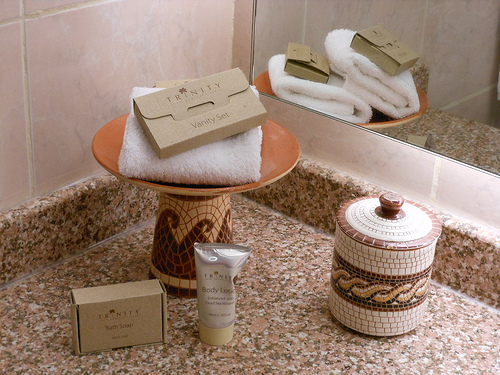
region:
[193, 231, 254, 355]
Squeezed tube on top of a counter.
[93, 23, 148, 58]
Squeezed tube on top of a counter.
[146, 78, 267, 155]
trinity is in a box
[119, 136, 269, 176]
the towewl is white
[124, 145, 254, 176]
the towel is folded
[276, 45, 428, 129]
towels are in the reflection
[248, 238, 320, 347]
the counter is marbled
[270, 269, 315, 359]
the counter is brown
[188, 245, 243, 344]
the bodylotion is upside down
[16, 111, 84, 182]
the wall is tiled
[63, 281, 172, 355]
the box is brown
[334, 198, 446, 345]
the container is brown and white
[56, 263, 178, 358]
a little box of soap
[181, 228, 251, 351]
a tube of beauty cream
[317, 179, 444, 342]
a round container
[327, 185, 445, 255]
cover of container is brown and white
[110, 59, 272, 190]
a small box over a white towel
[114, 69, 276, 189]
a folded white towel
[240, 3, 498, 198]
a mirror on right side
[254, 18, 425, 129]
two towels are reflected on mirror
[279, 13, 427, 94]
two brown boxes on white towels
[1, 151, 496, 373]
counter is color brown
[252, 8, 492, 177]
mirror above countertop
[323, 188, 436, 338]
jar with lid on counter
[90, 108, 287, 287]
stand with white towel on it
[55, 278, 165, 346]
cardboard soap box on counter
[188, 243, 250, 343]
squeeze bottle of lotion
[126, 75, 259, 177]
folded white towel on platter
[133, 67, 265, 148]
cardboard box on top of towel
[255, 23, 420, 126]
reflection of towels in mirror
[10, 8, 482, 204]
tiles on the bathroom walls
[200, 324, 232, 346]
cap of squeeze tube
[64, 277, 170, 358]
Small brown Trinity box on the counter.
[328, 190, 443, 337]
A decorative ceramic container with lid.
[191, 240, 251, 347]
A silver and yellow tube of body lotion.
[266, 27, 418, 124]
Two white folded hand towels in the orange dish reflecting in the mirror.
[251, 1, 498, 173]
A mirror on the right.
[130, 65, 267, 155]
The brown larger Trinity box on the top towel.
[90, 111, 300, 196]
Round top orange bowl.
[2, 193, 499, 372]
A speckled counter.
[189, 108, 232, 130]
Vanity set written on the larger cardboard box.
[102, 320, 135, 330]
Bath soap written on the brown box on the counter.